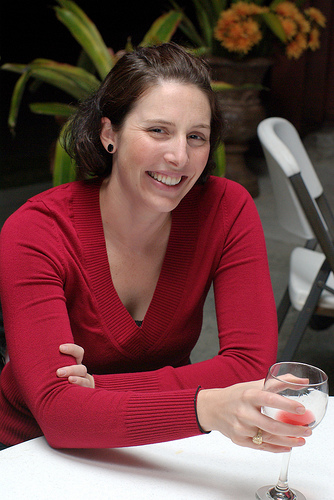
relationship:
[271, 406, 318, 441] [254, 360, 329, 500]
wine inside a glass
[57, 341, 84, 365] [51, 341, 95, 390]
finger curled on left hand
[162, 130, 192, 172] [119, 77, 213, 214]
nose on front of face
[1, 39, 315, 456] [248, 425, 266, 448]
woman wearing a ring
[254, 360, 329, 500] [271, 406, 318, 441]
glass holds wine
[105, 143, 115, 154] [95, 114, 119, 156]
earring worn in ear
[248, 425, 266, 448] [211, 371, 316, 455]
ring worn on hand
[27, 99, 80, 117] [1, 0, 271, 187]
leaf of a plant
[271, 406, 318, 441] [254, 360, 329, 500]
wine inside glass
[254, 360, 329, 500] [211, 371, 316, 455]
glass held in hand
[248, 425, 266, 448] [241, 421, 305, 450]
ring worn on finger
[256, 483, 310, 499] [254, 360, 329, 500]
base of glass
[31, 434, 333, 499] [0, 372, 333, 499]
shadow on top of table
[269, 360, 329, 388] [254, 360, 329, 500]
rim of glass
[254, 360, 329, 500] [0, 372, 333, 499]
glass on top of table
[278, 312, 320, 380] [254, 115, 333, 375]
leg of chair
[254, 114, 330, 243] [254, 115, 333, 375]
back of chair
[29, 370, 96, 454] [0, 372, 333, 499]
elbow on top of table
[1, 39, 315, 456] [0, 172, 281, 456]
woman wearing a sweater